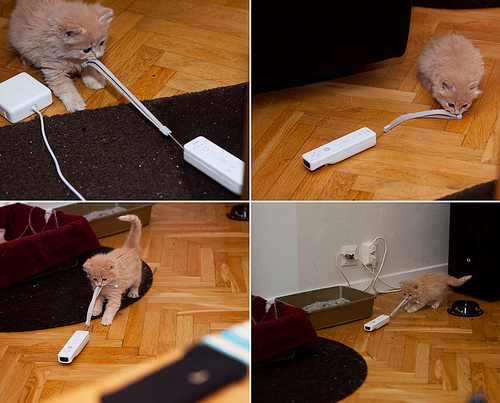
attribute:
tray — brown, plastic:
[276, 279, 376, 329]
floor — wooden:
[311, 282, 498, 399]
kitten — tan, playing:
[83, 212, 141, 324]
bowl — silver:
[449, 296, 481, 318]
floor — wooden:
[260, 287, 499, 401]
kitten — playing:
[88, 212, 144, 329]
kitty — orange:
[25, 20, 197, 115]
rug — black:
[6, 87, 231, 197]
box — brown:
[302, 259, 446, 353]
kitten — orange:
[84, 250, 143, 322]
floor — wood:
[249, 104, 498, 201]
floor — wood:
[403, 316, 464, 368]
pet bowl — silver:
[448, 299, 484, 316]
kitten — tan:
[78, 208, 150, 331]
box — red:
[252, 293, 319, 360]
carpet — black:
[253, 337, 370, 402]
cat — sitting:
[69, 226, 189, 317]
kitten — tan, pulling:
[8, 2, 113, 112]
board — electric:
[341, 242, 381, 269]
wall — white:
[264, 216, 396, 261]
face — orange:
[435, 82, 477, 120]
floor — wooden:
[370, 138, 468, 210]